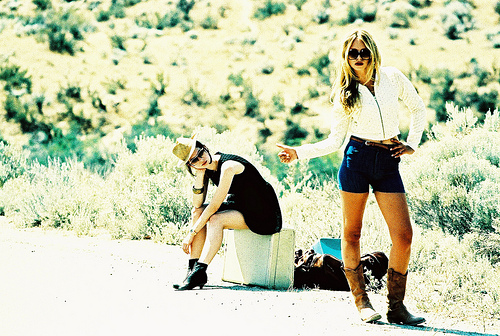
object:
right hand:
[188, 168, 208, 210]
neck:
[208, 148, 228, 173]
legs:
[372, 162, 428, 328]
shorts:
[333, 133, 409, 199]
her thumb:
[273, 141, 288, 149]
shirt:
[289, 64, 432, 161]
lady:
[269, 23, 435, 329]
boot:
[172, 260, 211, 292]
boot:
[383, 265, 429, 329]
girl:
[158, 129, 285, 294]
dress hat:
[169, 131, 203, 169]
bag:
[292, 244, 353, 293]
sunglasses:
[187, 148, 207, 164]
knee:
[390, 228, 415, 246]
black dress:
[200, 149, 283, 236]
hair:
[332, 26, 384, 111]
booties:
[173, 254, 212, 293]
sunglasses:
[346, 47, 373, 59]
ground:
[0, 4, 500, 319]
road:
[0, 208, 500, 336]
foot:
[321, 240, 385, 333]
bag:
[218, 222, 297, 292]